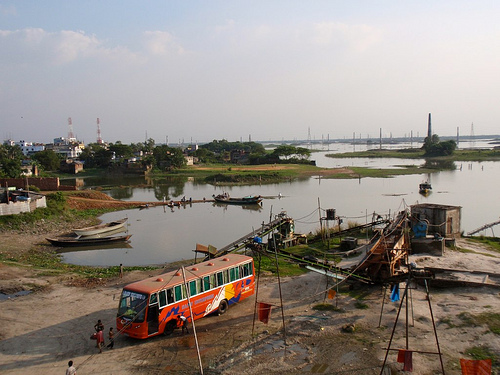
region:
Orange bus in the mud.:
[116, 251, 258, 336]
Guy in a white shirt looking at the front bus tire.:
[177, 315, 189, 336]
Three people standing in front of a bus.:
[89, 315, 116, 351]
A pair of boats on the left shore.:
[53, 222, 136, 250]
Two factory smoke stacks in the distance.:
[67, 116, 107, 144]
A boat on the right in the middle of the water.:
[415, 180, 431, 195]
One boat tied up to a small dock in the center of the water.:
[217, 193, 263, 207]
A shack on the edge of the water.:
[412, 200, 462, 235]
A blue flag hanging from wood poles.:
[391, 280, 402, 302]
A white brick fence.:
[0, 195, 57, 220]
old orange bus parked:
[108, 250, 268, 352]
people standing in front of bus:
[84, 313, 127, 355]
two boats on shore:
[41, 213, 138, 255]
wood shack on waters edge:
[402, 198, 469, 246]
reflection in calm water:
[141, 178, 208, 203]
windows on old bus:
[179, 267, 243, 309]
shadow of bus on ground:
[29, 305, 98, 356]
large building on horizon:
[24, 137, 86, 171]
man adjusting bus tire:
[170, 313, 195, 337]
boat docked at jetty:
[207, 186, 269, 212]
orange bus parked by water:
[107, 247, 262, 338]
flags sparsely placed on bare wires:
[221, 272, 408, 345]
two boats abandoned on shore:
[39, 213, 137, 254]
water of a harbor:
[100, 158, 477, 263]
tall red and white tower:
[52, 108, 104, 147]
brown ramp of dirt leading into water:
[50, 182, 192, 209]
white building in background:
[9, 133, 82, 165]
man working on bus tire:
[167, 313, 194, 335]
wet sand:
[225, 328, 352, 373]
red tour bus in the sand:
[106, 254, 267, 339]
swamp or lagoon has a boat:
[74, 158, 350, 293]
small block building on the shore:
[405, 190, 460, 240]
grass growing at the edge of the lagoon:
[55, 200, 115, 295]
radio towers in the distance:
[53, 108, 168, 167]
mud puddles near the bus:
[208, 307, 355, 374]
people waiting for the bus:
[71, 312, 124, 360]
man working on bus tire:
[166, 300, 196, 342]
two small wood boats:
[39, 212, 149, 255]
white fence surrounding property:
[4, 193, 66, 213]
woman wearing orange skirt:
[78, 311, 117, 357]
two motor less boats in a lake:
[45, 191, 147, 266]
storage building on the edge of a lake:
[369, 194, 476, 289]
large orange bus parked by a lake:
[70, 241, 262, 352]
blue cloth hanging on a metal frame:
[359, 250, 436, 340]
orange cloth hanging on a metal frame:
[232, 209, 319, 344]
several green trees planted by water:
[10, 126, 382, 201]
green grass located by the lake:
[25, 196, 375, 298]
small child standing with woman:
[96, 321, 124, 358]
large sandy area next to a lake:
[165, 254, 478, 374]